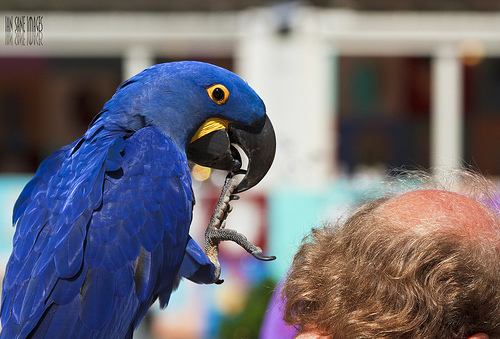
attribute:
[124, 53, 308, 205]
head — blue parrot's 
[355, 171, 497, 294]
bald spot —  balding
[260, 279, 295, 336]
purple background — Purple 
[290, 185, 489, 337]
hair — light brown 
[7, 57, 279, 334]
parrot — blue ,  blue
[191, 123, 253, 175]
mouth — open 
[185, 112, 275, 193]
parrot's beak — blue parrot's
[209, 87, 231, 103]
eyes — yellow 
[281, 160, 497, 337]
man — shoulder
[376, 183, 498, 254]
spot — man's bald 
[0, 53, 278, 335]
bird — black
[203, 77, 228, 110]
eye — Bird's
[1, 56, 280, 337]
blue bird — blue 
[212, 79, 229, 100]
eye — yellow 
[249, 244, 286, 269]
talon — blue, parrot's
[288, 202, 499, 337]
hair — blonde 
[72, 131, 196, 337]
right wing — blue parrot's right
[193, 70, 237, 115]
eye — bird's, Yellow